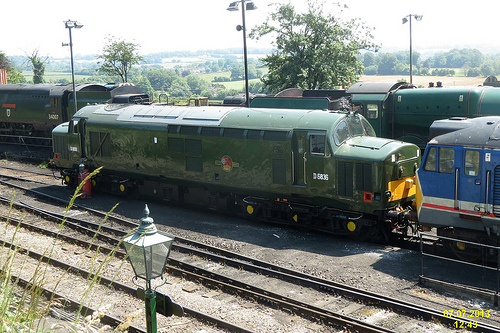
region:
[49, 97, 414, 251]
dark green railroad car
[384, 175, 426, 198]
yellow stripe on train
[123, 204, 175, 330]
green lamppost with glass hurricane cover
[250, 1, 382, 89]
green leaves on trees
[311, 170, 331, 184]
white numbers on side of train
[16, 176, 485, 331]
metal railroad tracks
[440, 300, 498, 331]
time stamp in corner of photo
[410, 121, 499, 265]
rear end of blue train car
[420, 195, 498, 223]
red stripe down side of train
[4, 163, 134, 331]
tall green weeds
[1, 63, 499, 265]
a bunch of different trains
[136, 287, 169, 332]
a green lamp post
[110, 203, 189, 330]
a lamp that is not on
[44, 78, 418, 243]
a green train engine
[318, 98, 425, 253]
the front of a train engine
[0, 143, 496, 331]
railroad tracks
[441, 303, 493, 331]
the time stamp of the picture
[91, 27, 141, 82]
a small tree with a little bit of leafs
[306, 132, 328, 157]
a small window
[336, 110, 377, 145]
the windshield of a train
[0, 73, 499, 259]
train cars are parked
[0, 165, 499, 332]
tracks next to train cars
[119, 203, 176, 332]
green street lamp next to tracks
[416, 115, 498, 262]
train car is blue, white, and red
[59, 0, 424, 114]
lights above the train cars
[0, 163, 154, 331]
tall grass in front of street light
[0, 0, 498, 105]
green trees behind train cars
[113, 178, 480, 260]
black wheels on train cars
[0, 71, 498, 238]
most of train cars are green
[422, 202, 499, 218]
red line on train car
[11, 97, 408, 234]
One green train engine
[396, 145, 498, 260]
train car of some sort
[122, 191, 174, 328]
Street lamp at the train track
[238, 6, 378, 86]
A tree on the other side of the tracks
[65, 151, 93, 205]
Some type of red box beside train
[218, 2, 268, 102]
Lamps on tall poles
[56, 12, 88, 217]
Lamps on tall poles at the railroad track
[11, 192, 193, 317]
Empty railroad tracks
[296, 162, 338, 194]
Numbers on the train engine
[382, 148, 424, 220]
yellow strip on back of train engine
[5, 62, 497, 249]
Trains in a train yard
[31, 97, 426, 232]
A greed train engine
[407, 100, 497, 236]
A blue train with a red stripe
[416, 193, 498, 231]
A red stripe on a train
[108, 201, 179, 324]
A street lamp near the tracks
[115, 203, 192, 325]
A green street lamp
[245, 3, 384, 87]
A tree near the train yard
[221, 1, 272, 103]
Lights on a pole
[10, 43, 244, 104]
Trees in the distance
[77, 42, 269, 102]
A scenic background